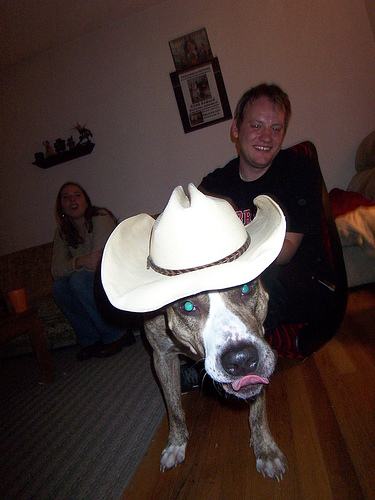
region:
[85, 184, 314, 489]
dog wearing white cowboy hat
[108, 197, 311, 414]
dog's eyes look blue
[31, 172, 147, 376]
girl sitting on couch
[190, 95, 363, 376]
buy sitting in gaming chair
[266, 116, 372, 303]
recliner chair behind person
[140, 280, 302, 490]
dog's tongue sticking out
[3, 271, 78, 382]
orange cup on coffee table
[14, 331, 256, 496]
grey striped rug next to dog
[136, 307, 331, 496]
dog standing on wood floor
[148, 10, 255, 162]
two pictures on the wall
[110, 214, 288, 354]
the dog is wearing a hat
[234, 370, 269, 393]
the tongue is pink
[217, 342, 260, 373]
the nose is black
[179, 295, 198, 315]
the eyes are torquise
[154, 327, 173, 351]
the dog is gray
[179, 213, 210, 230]
the hat is white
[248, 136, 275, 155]
he is smilinng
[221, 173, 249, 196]
the shirt is black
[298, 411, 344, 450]
the floor is brown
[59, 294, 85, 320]
the pants are blue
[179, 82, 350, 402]
a man sitting on the floor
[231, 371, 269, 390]
a pink tongue of a dog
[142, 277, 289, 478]
a gray dog standing in a living room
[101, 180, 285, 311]
a white cowboy hat on top of a dog's head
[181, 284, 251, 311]
dog with blue eyes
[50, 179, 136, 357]
a woman sitting on a couch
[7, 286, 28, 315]
an orange cup on a wooden table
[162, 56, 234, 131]
a framed newspaper article on the wall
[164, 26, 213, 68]
a painting on the wall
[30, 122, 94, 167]
knick knacks on a small shelf on the wall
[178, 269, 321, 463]
This is a dog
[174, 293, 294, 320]
These are two eyes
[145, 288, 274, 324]
The eyes are teal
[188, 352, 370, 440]
This is a mouth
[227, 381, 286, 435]
The tongue is pink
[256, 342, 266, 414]
This is a tongue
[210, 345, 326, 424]
This is a nose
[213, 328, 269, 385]
The nose is black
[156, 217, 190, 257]
This is a cowboy hat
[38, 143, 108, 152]
This is a shelf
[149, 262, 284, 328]
the eyes are brown in colour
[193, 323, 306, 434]
the tongue is red in colour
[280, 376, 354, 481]
the floor is brown in colour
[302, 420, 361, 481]
the floor is wooden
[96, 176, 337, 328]
the hat is white in colur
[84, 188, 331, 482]
the dog is standing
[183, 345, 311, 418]
the tongue is out of the mouth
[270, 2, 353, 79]
the wall is white in colour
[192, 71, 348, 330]
the man is seated down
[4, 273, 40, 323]
a red cup on the table